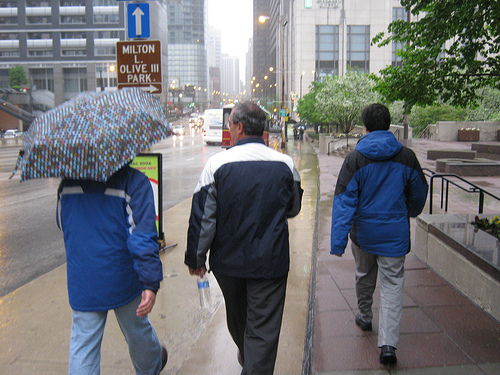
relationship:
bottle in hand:
[197, 269, 211, 309] [182, 249, 212, 279]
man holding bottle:
[182, 93, 311, 373] [194, 265, 214, 312]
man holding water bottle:
[326, 102, 427, 372] [192, 271, 216, 315]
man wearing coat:
[326, 102, 427, 372] [330, 130, 428, 256]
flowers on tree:
[308, 62, 365, 122] [290, 69, 396, 150]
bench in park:
[423, 143, 479, 163] [308, 95, 498, 299]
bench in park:
[434, 153, 497, 185] [308, 95, 498, 299]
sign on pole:
[104, 37, 179, 103] [111, 0, 168, 250]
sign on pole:
[121, 0, 150, 40] [121, 0, 165, 262]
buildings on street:
[2, 0, 487, 114] [2, 126, 313, 362]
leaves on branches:
[366, 0, 492, 115] [366, 3, 497, 119]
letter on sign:
[119, 42, 130, 54] [115, 40, 163, 96]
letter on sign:
[131, 43, 138, 54] [115, 40, 163, 96]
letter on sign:
[141, 42, 147, 54] [115, 40, 163, 96]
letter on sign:
[118, 64, 125, 73] [115, 40, 163, 96]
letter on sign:
[134, 64, 141, 71] [115, 40, 163, 96]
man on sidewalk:
[326, 102, 427, 372] [302, 119, 379, 373]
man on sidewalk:
[185, 100, 304, 375] [302, 119, 379, 373]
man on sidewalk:
[56, 138, 172, 371] [302, 119, 379, 373]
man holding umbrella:
[54, 165, 166, 375] [15, 52, 193, 192]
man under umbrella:
[54, 165, 166, 375] [9, 89, 173, 179]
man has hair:
[328, 103, 428, 367] [360, 103, 391, 143]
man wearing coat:
[328, 103, 428, 367] [329, 130, 429, 257]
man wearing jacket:
[182, 93, 311, 373] [177, 139, 305, 278]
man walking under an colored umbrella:
[54, 165, 166, 375] [8, 86, 177, 183]